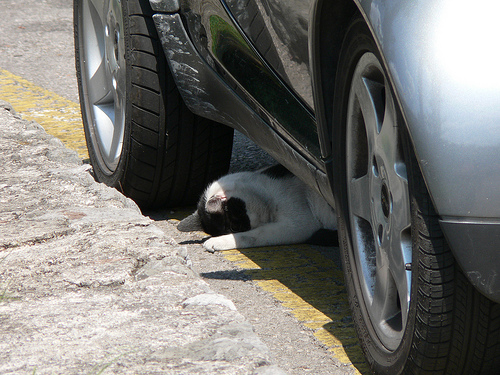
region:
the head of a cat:
[175, 178, 287, 259]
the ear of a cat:
[158, 175, 281, 256]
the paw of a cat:
[192, 227, 249, 301]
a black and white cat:
[138, 167, 262, 275]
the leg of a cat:
[206, 198, 298, 261]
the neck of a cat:
[226, 156, 296, 233]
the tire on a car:
[300, 57, 481, 370]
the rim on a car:
[340, 111, 452, 334]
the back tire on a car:
[63, 15, 219, 218]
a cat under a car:
[147, 85, 371, 292]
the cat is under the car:
[151, 142, 355, 299]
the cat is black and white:
[167, 159, 325, 266]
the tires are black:
[325, 35, 443, 337]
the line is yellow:
[2, 50, 82, 160]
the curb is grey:
[18, 187, 252, 355]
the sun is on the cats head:
[183, 156, 230, 246]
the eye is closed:
[177, 212, 257, 242]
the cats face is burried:
[170, 171, 277, 255]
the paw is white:
[190, 230, 238, 260]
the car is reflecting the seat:
[236, 1, 338, 129]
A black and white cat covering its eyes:
[173, 167, 300, 257]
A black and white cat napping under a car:
[76, 29, 361, 349]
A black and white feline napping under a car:
[108, 64, 368, 301]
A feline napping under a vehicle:
[148, 138, 363, 263]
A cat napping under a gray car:
[173, 133, 367, 266]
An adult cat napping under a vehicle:
[156, 145, 382, 292]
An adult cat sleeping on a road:
[171, 160, 326, 295]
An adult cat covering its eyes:
[175, 167, 285, 252]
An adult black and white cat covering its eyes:
[172, 162, 292, 267]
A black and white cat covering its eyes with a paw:
[180, 166, 289, 255]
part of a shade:
[297, 272, 337, 329]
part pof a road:
[271, 308, 291, 351]